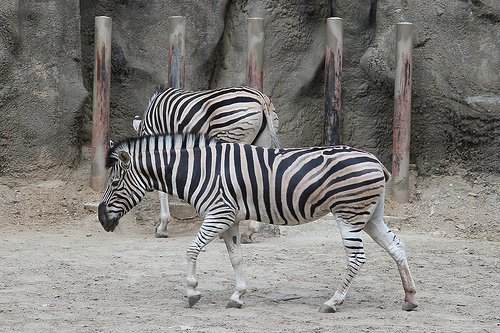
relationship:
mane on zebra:
[113, 130, 253, 162] [75, 129, 499, 326]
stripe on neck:
[137, 152, 149, 190] [140, 133, 208, 208]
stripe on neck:
[174, 143, 189, 200] [140, 133, 208, 208]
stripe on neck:
[161, 137, 169, 187] [140, 133, 208, 208]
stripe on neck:
[152, 151, 162, 187] [140, 133, 208, 208]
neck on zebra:
[140, 133, 208, 208] [60, 101, 479, 321]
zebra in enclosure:
[60, 101, 479, 321] [0, 1, 497, 329]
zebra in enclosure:
[134, 81, 284, 241] [0, 1, 497, 329]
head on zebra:
[98, 136, 144, 232] [60, 101, 479, 321]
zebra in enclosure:
[60, 101, 479, 321] [12, 64, 497, 309]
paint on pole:
[326, 39, 364, 113] [322, 15, 345, 146]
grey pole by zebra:
[92, 15, 109, 177] [134, 81, 284, 241]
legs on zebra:
[178, 206, 253, 314] [60, 101, 479, 321]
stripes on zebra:
[238, 184, 325, 223] [60, 101, 479, 321]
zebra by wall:
[134, 81, 284, 241] [1, 0, 499, 189]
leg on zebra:
[153, 190, 173, 240] [134, 81, 284, 241]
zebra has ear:
[60, 101, 479, 321] [113, 149, 134, 166]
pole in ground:
[381, 27, 433, 168] [3, 173, 496, 331]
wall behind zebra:
[1, 0, 499, 189] [134, 81, 284, 241]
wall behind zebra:
[1, 0, 499, 189] [60, 101, 479, 321]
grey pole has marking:
[89, 14, 114, 192] [92, 43, 112, 154]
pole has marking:
[163, 15, 191, 87] [165, 28, 185, 87]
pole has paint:
[317, 16, 351, 145] [322, 45, 343, 147]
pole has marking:
[322, 15, 345, 146] [390, 50, 417, 180]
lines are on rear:
[224, 122, 252, 139] [195, 84, 285, 142]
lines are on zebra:
[224, 122, 252, 139] [134, 81, 284, 241]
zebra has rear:
[134, 81, 284, 241] [195, 84, 285, 142]